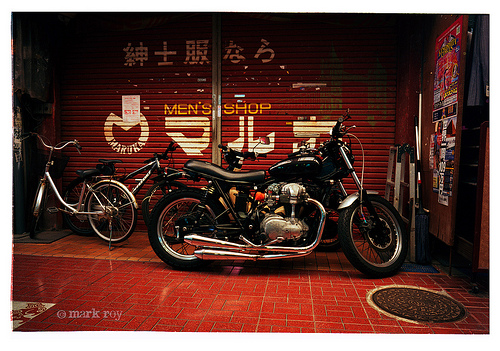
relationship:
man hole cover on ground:
[367, 283, 468, 325] [19, 224, 490, 331]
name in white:
[58, 301, 132, 320] [60, 309, 129, 321]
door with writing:
[64, 19, 400, 204] [105, 29, 344, 161]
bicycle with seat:
[17, 130, 142, 247] [76, 164, 110, 176]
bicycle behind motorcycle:
[17, 130, 142, 247] [145, 102, 412, 277]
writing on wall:
[105, 29, 344, 161] [60, 11, 396, 186]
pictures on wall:
[423, 21, 466, 208] [417, 15, 467, 243]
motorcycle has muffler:
[145, 102, 412, 277] [181, 198, 328, 265]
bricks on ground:
[15, 225, 492, 324] [19, 224, 490, 331]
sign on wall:
[88, 30, 322, 169] [60, 11, 396, 186]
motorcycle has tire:
[145, 102, 412, 277] [337, 191, 411, 277]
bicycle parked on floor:
[17, 130, 142, 247] [16, 213, 490, 331]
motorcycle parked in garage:
[145, 102, 412, 277] [20, 25, 485, 326]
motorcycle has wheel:
[145, 102, 412, 277] [338, 188, 410, 273]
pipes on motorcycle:
[184, 199, 327, 261] [145, 102, 412, 277]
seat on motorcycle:
[184, 150, 269, 178] [145, 102, 412, 277]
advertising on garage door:
[429, 20, 465, 204] [416, 15, 479, 251]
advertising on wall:
[429, 20, 465, 204] [417, 15, 467, 243]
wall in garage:
[417, 15, 467, 243] [20, 25, 485, 326]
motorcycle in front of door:
[145, 102, 412, 277] [64, 19, 400, 204]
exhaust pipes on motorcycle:
[181, 196, 330, 261] [145, 102, 412, 277]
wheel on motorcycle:
[338, 188, 410, 273] [145, 102, 412, 277]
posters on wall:
[427, 17, 468, 207] [417, 15, 467, 243]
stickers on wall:
[427, 19, 466, 207] [417, 15, 467, 243]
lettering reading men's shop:
[158, 100, 275, 118] [163, 97, 274, 118]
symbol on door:
[100, 91, 344, 160] [64, 19, 400, 204]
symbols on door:
[114, 28, 278, 74] [64, 19, 400, 204]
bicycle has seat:
[17, 130, 142, 247] [76, 164, 110, 176]